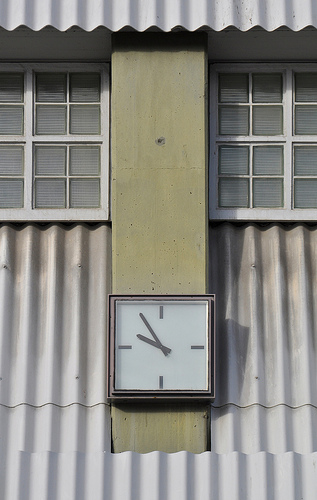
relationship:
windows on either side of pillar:
[2, 57, 313, 202] [96, 36, 218, 218]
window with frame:
[26, 67, 101, 206] [206, 60, 219, 217]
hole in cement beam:
[157, 136, 166, 146] [123, 48, 212, 158]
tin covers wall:
[2, 225, 315, 486] [0, 55, 309, 482]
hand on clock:
[138, 312, 168, 357] [106, 294, 211, 394]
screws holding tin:
[77, 264, 81, 268] [2, 222, 315, 500]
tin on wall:
[2, 222, 315, 500] [1, 1, 311, 496]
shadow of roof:
[111, 34, 207, 51] [1, 1, 316, 30]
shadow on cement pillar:
[111, 34, 207, 51] [111, 30, 206, 454]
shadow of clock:
[213, 315, 249, 404] [106, 294, 211, 394]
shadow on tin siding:
[213, 315, 249, 404] [203, 224, 314, 406]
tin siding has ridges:
[0, 222, 111, 498] [42, 219, 65, 453]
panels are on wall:
[215, 222, 314, 447] [0, 226, 102, 496]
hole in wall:
[148, 137, 169, 149] [129, 177, 186, 229]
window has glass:
[211, 65, 312, 217] [216, 140, 251, 173]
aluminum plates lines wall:
[209, 224, 314, 451] [1, 1, 311, 496]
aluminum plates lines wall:
[1, 221, 109, 451] [1, 1, 311, 496]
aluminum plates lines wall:
[0, 451, 316, 499] [1, 1, 311, 496]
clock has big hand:
[102, 288, 217, 404] [140, 302, 171, 352]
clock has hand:
[102, 288, 217, 404] [136, 332, 171, 356]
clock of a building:
[77, 308, 215, 404] [1, 33, 316, 497]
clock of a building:
[102, 288, 217, 404] [1, 33, 316, 497]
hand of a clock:
[136, 332, 171, 356] [105, 292, 216, 400]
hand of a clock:
[138, 312, 168, 357] [105, 292, 216, 400]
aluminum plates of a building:
[1, 221, 109, 451] [1, 33, 316, 497]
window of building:
[211, 65, 312, 217] [1, 33, 316, 497]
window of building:
[0, 59, 102, 209] [1, 33, 316, 497]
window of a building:
[211, 65, 312, 217] [1, 33, 316, 497]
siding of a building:
[3, 3, 316, 36] [1, 33, 316, 497]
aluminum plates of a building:
[209, 224, 314, 451] [1, 33, 316, 497]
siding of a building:
[2, 407, 313, 495] [1, 33, 316, 497]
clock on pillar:
[102, 288, 217, 404] [112, 48, 209, 440]